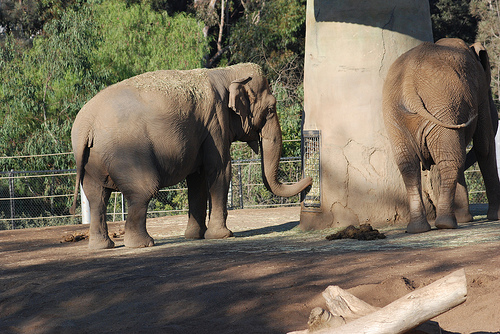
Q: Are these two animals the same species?
A: Yes, all the animals are elephants.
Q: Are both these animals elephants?
A: Yes, all the animals are elephants.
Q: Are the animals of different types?
A: No, all the animals are elephants.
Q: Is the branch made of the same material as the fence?
A: No, the branch is made of wood and the fence is made of metal.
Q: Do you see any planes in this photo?
A: No, there are no planes.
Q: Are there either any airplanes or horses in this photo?
A: No, there are no airplanes or horses.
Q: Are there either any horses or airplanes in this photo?
A: No, there are no airplanes or horses.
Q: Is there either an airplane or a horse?
A: No, there are no airplanes or horses.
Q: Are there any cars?
A: No, there are no cars.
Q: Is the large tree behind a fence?
A: Yes, the tree is behind a fence.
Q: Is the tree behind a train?
A: No, the tree is behind a fence.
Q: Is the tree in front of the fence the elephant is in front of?
A: No, the tree is behind the fence.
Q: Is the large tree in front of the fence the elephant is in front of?
A: No, the tree is behind the fence.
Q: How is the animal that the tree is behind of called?
A: The animal is an elephant.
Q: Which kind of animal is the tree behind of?
A: The tree is behind the elephant.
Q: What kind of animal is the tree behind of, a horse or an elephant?
A: The tree is behind an elephant.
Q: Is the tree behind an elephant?
A: Yes, the tree is behind an elephant.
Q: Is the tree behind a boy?
A: No, the tree is behind an elephant.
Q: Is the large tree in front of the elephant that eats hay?
A: No, the tree is behind the elephant.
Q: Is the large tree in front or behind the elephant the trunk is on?
A: The tree is behind the elephant.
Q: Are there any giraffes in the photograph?
A: No, there are no giraffes.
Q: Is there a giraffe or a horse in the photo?
A: No, there are no giraffes or horses.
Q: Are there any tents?
A: No, there are no tents.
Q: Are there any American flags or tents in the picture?
A: No, there are no tents or American flags.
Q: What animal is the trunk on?
A: The trunk is on the elephant.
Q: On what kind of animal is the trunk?
A: The trunk is on the elephant.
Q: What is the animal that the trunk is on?
A: The animal is an elephant.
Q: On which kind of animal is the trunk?
A: The trunk is on the elephant.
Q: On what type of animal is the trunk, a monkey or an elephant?
A: The trunk is on an elephant.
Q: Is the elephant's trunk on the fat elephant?
A: Yes, the trunk is on the elephant.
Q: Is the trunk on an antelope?
A: No, the trunk is on the elephant.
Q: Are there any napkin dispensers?
A: No, there are no napkin dispensers.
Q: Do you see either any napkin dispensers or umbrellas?
A: No, there are no napkin dispensers or umbrellas.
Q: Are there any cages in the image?
A: No, there are no cages.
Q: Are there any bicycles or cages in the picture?
A: No, there are no cages or bicycles.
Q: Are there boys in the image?
A: No, there are no boys.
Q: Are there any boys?
A: No, there are no boys.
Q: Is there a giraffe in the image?
A: No, there are no giraffes.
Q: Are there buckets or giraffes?
A: No, there are no giraffes or buckets.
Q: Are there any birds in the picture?
A: No, there are no birds.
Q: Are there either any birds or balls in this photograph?
A: No, there are no birds or balls.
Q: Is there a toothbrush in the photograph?
A: No, there are no toothbrushes.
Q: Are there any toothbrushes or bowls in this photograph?
A: No, there are no toothbrushes or bowls.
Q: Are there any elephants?
A: Yes, there is an elephant.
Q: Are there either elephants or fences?
A: Yes, there is an elephant.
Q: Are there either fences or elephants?
A: Yes, there is an elephant.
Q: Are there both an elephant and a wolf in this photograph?
A: No, there is an elephant but no wolves.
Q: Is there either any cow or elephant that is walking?
A: Yes, the elephant is walking.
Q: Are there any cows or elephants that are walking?
A: Yes, the elephant is walking.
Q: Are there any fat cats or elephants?
A: Yes, there is a fat elephant.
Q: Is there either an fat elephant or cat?
A: Yes, there is a fat elephant.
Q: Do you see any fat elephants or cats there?
A: Yes, there is a fat elephant.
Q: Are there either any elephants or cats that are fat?
A: Yes, the elephant is fat.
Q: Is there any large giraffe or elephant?
A: Yes, there is a large elephant.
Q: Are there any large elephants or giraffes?
A: Yes, there is a large elephant.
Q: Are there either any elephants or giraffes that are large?
A: Yes, the elephant is large.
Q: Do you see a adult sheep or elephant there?
A: Yes, there is an adult elephant.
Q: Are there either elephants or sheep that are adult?
A: Yes, the elephant is adult.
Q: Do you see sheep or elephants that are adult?
A: Yes, the elephant is adult.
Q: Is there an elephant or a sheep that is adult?
A: Yes, the elephant is adult.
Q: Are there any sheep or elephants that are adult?
A: Yes, the elephant is adult.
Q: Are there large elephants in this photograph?
A: Yes, there is a large elephant.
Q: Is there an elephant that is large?
A: Yes, there is an elephant that is large.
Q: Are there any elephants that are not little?
A: Yes, there is a large elephant.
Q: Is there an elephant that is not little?
A: Yes, there is a large elephant.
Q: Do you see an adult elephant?
A: Yes, there is an adult elephant.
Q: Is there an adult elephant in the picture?
A: Yes, there is an adult elephant.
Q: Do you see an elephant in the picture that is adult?
A: Yes, there is an elephant that is adult.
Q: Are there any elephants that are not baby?
A: Yes, there is a adult elephant.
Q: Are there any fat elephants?
A: Yes, there is a fat elephant.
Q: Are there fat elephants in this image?
A: Yes, there is a fat elephant.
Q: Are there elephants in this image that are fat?
A: Yes, there is a fat elephant.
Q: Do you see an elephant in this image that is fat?
A: Yes, there is an elephant that is fat.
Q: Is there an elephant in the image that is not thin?
A: Yes, there is a fat elephant.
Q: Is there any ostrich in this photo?
A: No, there are no ostriches.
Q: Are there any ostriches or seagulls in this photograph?
A: No, there are no ostriches or seagulls.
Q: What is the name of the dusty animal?
A: The animal is an elephant.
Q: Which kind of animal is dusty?
A: The animal is an elephant.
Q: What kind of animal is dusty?
A: The animal is an elephant.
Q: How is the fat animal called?
A: The animal is an elephant.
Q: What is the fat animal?
A: The animal is an elephant.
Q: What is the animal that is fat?
A: The animal is an elephant.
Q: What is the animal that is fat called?
A: The animal is an elephant.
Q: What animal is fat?
A: The animal is an elephant.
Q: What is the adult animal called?
A: The animal is an elephant.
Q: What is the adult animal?
A: The animal is an elephant.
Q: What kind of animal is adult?
A: The animal is an elephant.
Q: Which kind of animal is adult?
A: The animal is an elephant.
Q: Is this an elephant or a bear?
A: This is an elephant.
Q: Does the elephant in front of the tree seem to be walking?
A: Yes, the elephant is walking.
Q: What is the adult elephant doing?
A: The elephant is walking.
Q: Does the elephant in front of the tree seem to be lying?
A: No, the elephant is walking.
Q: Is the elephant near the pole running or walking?
A: The elephant is walking.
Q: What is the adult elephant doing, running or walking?
A: The elephant is walking.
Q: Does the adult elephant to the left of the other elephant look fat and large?
A: Yes, the elephant is fat and large.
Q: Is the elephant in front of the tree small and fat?
A: No, the elephant is fat but large.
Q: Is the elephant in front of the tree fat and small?
A: No, the elephant is fat but large.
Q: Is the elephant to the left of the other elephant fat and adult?
A: Yes, the elephant is fat and adult.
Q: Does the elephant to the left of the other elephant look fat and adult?
A: Yes, the elephant is fat and adult.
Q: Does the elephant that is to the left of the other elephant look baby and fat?
A: No, the elephant is fat but adult.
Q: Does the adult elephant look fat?
A: Yes, the elephant is fat.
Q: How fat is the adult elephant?
A: The elephant is fat.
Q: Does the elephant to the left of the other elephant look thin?
A: No, the elephant is fat.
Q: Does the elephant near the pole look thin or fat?
A: The elephant is fat.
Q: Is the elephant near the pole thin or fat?
A: The elephant is fat.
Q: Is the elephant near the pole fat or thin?
A: The elephant is fat.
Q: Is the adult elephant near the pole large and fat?
A: Yes, the elephant is large and fat.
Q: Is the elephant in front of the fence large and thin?
A: No, the elephant is large but fat.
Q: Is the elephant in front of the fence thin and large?
A: No, the elephant is large but fat.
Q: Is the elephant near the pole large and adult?
A: Yes, the elephant is large and adult.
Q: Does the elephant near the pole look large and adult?
A: Yes, the elephant is large and adult.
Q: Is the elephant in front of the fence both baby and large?
A: No, the elephant is large but adult.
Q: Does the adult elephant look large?
A: Yes, the elephant is large.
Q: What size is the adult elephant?
A: The elephant is large.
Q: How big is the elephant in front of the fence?
A: The elephant is large.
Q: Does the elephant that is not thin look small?
A: No, the elephant is large.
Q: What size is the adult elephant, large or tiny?
A: The elephant is large.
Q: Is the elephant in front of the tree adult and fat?
A: Yes, the elephant is adult and fat.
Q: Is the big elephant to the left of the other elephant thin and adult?
A: No, the elephant is adult but fat.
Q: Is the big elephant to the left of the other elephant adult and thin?
A: No, the elephant is adult but fat.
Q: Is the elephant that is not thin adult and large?
A: Yes, the elephant is adult and large.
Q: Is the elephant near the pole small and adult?
A: No, the elephant is adult but large.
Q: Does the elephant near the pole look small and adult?
A: No, the elephant is adult but large.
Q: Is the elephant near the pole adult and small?
A: No, the elephant is adult but large.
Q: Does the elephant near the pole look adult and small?
A: No, the elephant is adult but large.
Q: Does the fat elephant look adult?
A: Yes, the elephant is adult.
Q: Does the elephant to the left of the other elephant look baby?
A: No, the elephant is adult.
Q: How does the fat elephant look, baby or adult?
A: The elephant is adult.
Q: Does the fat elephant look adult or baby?
A: The elephant is adult.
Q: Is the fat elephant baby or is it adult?
A: The elephant is adult.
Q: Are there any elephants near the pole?
A: Yes, there is an elephant near the pole.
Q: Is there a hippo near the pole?
A: No, there is an elephant near the pole.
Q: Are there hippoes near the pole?
A: No, there is an elephant near the pole.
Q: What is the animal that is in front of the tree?
A: The animal is an elephant.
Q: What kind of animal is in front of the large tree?
A: The animal is an elephant.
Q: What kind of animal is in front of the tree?
A: The animal is an elephant.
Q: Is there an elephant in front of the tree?
A: Yes, there is an elephant in front of the tree.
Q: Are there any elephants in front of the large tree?
A: Yes, there is an elephant in front of the tree.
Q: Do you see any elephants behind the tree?
A: No, the elephant is in front of the tree.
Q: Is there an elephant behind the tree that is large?
A: No, the elephant is in front of the tree.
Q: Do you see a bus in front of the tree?
A: No, there is an elephant in front of the tree.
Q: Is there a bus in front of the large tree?
A: No, there is an elephant in front of the tree.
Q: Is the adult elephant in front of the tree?
A: Yes, the elephant is in front of the tree.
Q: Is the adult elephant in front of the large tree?
A: Yes, the elephant is in front of the tree.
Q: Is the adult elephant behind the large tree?
A: No, the elephant is in front of the tree.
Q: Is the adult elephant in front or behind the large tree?
A: The elephant is in front of the tree.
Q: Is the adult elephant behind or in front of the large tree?
A: The elephant is in front of the tree.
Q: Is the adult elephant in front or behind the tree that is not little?
A: The elephant is in front of the tree.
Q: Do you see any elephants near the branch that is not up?
A: Yes, there is an elephant near the branch.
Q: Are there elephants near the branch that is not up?
A: Yes, there is an elephant near the branch.